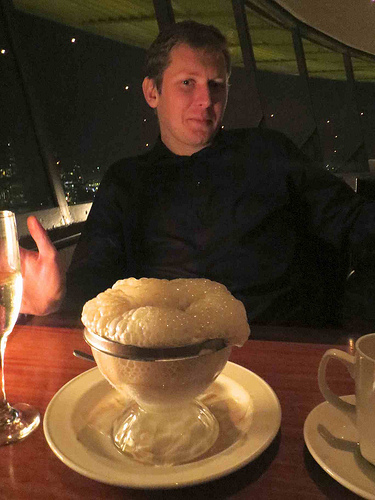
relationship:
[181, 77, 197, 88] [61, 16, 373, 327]
eye of man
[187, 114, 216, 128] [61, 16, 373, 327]
mouth of man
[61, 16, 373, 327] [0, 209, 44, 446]
man near glass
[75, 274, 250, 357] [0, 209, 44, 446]
foam near glass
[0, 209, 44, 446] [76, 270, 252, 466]
glass near dessert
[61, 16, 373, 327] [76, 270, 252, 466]
man looking at dessert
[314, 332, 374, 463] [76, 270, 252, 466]
cup near dessert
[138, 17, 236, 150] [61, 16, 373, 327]
head of man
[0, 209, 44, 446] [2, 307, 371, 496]
glass sitting on table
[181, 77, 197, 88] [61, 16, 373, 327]
eye of a man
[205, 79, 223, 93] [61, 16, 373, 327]
eye of a man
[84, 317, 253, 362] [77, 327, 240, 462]
rim of bowl